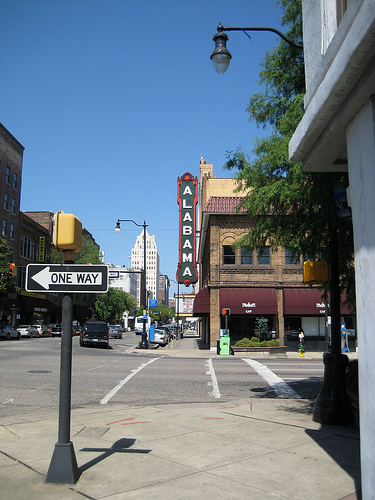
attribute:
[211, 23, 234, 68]
light — big, black, metal, yellow, vintage, round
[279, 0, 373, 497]
wall — white, historic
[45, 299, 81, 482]
pole — black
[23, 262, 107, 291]
street sign — black, rectangular, one way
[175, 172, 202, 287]
board — tall, red, green, burgundy, large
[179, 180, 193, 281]
business name — white, alabama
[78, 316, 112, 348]
car — black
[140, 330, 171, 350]
vehicle — parked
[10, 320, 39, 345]
vehicle — parked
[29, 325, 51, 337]
vehicle — parked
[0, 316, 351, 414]
road — gray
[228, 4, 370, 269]
tree — small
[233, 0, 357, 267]
leave — dark green, thick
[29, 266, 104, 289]
arrow — white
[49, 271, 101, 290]
text — black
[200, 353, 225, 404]
line — white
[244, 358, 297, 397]
line — white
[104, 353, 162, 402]
line — white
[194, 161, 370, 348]
building — tan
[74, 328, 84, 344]
light — red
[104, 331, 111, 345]
light — red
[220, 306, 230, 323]
light — red, illuminated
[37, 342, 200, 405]
intersection — empty, small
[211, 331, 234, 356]
box — green, green}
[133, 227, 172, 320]
building — white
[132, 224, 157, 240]
top — pointed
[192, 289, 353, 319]
awning — maroon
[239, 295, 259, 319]
text — white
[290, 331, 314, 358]
hydrant — yellow, green